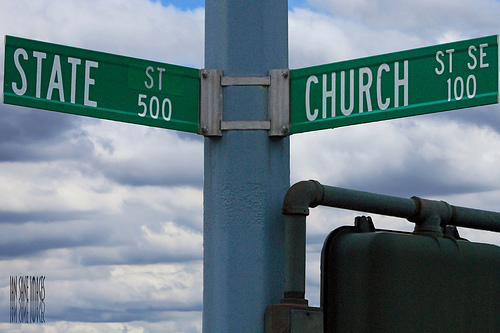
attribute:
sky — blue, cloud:
[1, 0, 489, 332]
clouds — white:
[2, 0, 500, 317]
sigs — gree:
[3, 34, 496, 127]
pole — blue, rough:
[204, 1, 292, 331]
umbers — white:
[137, 92, 173, 120]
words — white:
[14, 47, 103, 114]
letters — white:
[305, 63, 412, 125]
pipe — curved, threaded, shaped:
[273, 172, 466, 328]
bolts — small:
[198, 72, 216, 138]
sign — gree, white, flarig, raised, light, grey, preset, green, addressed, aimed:
[6, 34, 207, 136]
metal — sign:
[201, 70, 293, 141]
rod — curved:
[325, 220, 498, 329]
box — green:
[322, 219, 500, 324]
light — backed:
[205, 3, 274, 276]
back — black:
[333, 222, 500, 332]